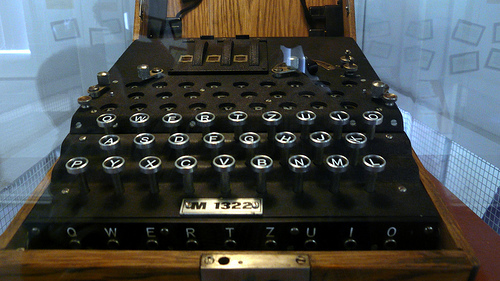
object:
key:
[96, 107, 120, 128]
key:
[250, 156, 277, 176]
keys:
[324, 150, 346, 172]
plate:
[181, 195, 267, 220]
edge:
[6, 245, 466, 268]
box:
[3, 0, 478, 278]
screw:
[202, 252, 218, 267]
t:
[223, 222, 237, 240]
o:
[381, 222, 401, 242]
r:
[180, 220, 196, 242]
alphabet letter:
[64, 157, 88, 169]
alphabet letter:
[101, 155, 125, 167]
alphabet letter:
[360, 154, 384, 172]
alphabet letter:
[260, 222, 280, 238]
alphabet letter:
[381, 226, 399, 239]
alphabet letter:
[196, 112, 217, 126]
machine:
[23, 35, 443, 249]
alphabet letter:
[235, 131, 264, 148]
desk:
[2, 67, 499, 281]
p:
[65, 151, 92, 177]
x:
[140, 149, 161, 175]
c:
[170, 149, 198, 173]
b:
[247, 153, 277, 170]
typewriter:
[30, 35, 446, 247]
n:
[288, 150, 318, 175]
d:
[173, 132, 193, 147]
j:
[306, 127, 334, 149]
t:
[228, 106, 253, 122]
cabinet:
[135, 5, 352, 38]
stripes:
[145, 10, 344, 33]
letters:
[139, 226, 166, 249]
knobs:
[238, 130, 272, 153]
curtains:
[359, 0, 499, 231]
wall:
[386, 19, 496, 226]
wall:
[3, 39, 84, 112]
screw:
[296, 254, 316, 264]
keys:
[329, 109, 359, 124]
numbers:
[179, 194, 262, 213]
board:
[22, 107, 440, 249]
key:
[63, 154, 90, 179]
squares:
[157, 35, 276, 74]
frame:
[39, 52, 446, 279]